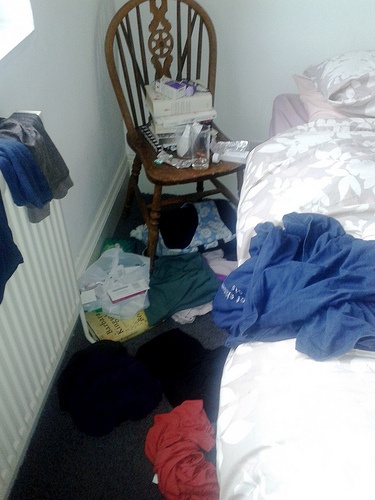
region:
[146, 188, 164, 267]
leg of the chair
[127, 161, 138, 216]
leg of the chair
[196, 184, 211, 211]
leg of the chair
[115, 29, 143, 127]
spindle of the chair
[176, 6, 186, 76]
spindle of the chair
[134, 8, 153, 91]
spindle of the chair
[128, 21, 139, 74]
spindle of the chair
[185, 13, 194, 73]
spindle of the chair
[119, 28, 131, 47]
spindle of the chair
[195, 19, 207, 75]
spindle of the chair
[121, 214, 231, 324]
Articles of clothing on floor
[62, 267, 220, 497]
Articles of clothing on floor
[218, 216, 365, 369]
Articles of clothing on bed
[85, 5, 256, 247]
Small brown chair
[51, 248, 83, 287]
Small part of white wall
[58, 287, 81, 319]
Small part of white wall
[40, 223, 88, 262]
Small part of white wall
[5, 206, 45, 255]
Small part of white wall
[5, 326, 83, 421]
Small part of white wall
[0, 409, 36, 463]
Small part of white wall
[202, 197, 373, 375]
Clothing on the bed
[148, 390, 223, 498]
Red shirt on the floor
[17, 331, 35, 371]
Molding on the wall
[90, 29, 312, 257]
Wooden chair in the corner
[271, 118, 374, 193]
Bedding has leaves on it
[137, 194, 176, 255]
Leg on the chair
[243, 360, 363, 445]
Light shining on the bed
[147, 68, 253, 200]
Stuff stacked on the chair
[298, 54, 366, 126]
Pillow on the bed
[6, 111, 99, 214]
Clothing hanging over wall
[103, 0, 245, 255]
a wooden chair is next to the bed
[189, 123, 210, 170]
an empty glass in on the chair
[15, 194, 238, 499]
the floor is carpeted with a dark color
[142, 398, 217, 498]
an orange article of clothing is on the floor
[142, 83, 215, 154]
a stack of books is on the chair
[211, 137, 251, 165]
plastic bottles are on the chair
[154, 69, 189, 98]
a box is on the book stack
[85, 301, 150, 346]
a hard cover book is on the carpet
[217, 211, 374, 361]
an article of blue clothing is on the bed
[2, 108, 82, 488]
clothes are on the wall heater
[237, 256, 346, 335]
navy blue shirt on top of bed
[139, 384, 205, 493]
red shirt thrown on floor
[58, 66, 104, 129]
white area on wall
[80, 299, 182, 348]
yellow book lying on bedroom floor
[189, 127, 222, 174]
empty glass sitting on chair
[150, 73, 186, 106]
medicine box sitting on chair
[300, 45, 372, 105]
white and grey floral pattern on pillow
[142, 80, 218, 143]
pile of books on chair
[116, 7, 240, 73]
brown chair sitting next to bed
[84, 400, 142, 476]
dark area of carpet on floor